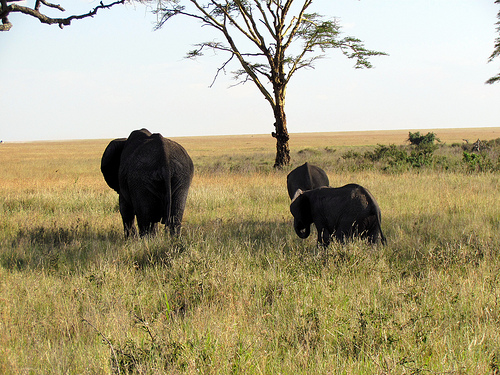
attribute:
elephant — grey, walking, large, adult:
[102, 130, 191, 248]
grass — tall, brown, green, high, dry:
[1, 137, 498, 375]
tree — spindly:
[163, 1, 385, 171]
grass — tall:
[38, 247, 485, 348]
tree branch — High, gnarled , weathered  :
[0, 0, 132, 30]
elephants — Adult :
[92, 120, 193, 236]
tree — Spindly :
[148, 3, 386, 182]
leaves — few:
[354, 59, 373, 69]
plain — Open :
[1, 128, 499, 373]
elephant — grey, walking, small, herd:
[284, 186, 385, 251]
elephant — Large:
[98, 127, 196, 245]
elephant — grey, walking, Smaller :
[283, 161, 330, 200]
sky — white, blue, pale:
[0, 0, 498, 143]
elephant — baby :
[257, 185, 402, 261]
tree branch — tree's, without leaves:
[0, 0, 142, 35]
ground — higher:
[1, 122, 497, 373]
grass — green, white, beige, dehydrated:
[39, 100, 488, 357]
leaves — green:
[301, 12, 363, 64]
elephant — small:
[288, 182, 386, 245]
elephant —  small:
[286, 162, 328, 199]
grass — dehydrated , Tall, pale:
[132, 211, 496, 342]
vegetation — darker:
[340, 126, 498, 176]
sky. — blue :
[5, 7, 488, 135]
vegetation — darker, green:
[407, 128, 441, 151]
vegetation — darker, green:
[460, 140, 490, 169]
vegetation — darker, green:
[322, 141, 341, 157]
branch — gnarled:
[40, 1, 115, 37]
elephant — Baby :
[283, 171, 397, 258]